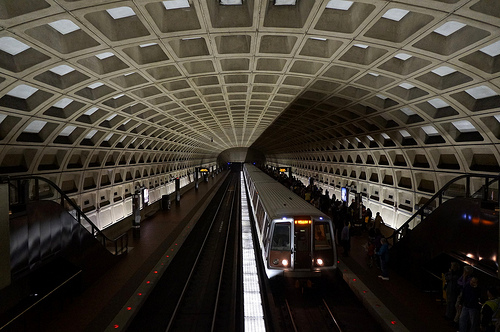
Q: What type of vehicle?
A: Train.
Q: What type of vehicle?
A: Train.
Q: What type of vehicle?
A: Train.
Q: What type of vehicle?
A: Train.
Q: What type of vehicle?
A: Train.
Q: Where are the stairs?
A: Near the walls.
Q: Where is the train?
A: On the track.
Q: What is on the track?
A: The train.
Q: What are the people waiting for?
A: The train.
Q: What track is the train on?
A: The right one.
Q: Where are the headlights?
A: On the train.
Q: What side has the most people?
A: The right side.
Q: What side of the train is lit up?
A: The front.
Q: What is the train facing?
A: The camera.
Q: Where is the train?
A: At the tracks.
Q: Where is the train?
A: At the station.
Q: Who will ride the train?
A: Passengers.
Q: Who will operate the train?
A: The conductor.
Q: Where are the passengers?
A: On the platform.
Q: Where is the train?
A: The tracks.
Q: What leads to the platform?
A: The escalator.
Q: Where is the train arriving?
A: The station.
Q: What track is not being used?
A: Left track.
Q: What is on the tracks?
A: A train.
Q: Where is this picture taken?
A: A train station.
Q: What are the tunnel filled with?
A: Passengers.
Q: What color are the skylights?
A: White.